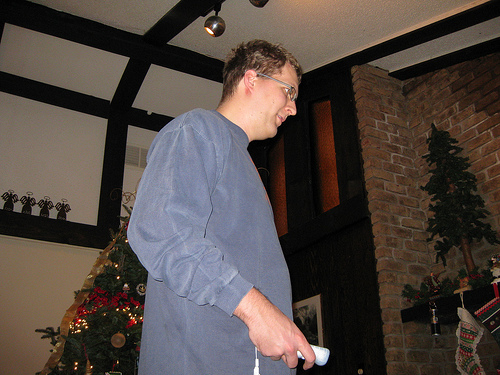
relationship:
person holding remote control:
[124, 38, 332, 374] [285, 340, 332, 367]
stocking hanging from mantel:
[450, 291, 487, 374] [400, 280, 499, 323]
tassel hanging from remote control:
[250, 346, 262, 374] [285, 340, 332, 367]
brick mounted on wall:
[400, 217, 424, 231] [352, 64, 479, 374]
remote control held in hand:
[285, 340, 332, 367] [244, 298, 317, 372]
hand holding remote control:
[244, 298, 317, 372] [285, 340, 332, 367]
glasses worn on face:
[244, 69, 298, 101] [267, 62, 300, 140]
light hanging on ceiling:
[200, 2, 226, 38] [0, 0, 498, 76]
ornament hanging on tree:
[109, 329, 126, 347] [36, 203, 148, 374]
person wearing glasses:
[124, 38, 332, 374] [244, 69, 298, 101]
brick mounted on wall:
[357, 124, 389, 143] [352, 64, 479, 374]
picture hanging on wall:
[290, 290, 325, 348] [251, 60, 388, 374]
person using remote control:
[124, 38, 332, 374] [285, 340, 332, 367]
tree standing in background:
[36, 203, 148, 374] [0, 15, 230, 373]